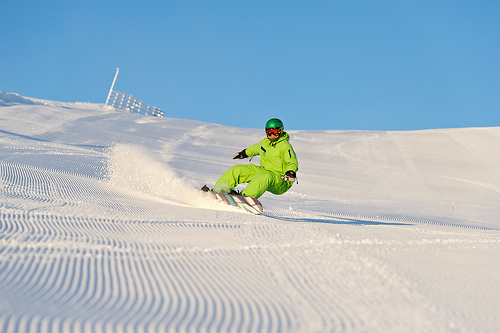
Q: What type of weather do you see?
A: It is clear.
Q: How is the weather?
A: It is clear.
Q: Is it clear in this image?
A: Yes, it is clear.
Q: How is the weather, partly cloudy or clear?
A: It is clear.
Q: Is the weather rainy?
A: No, it is clear.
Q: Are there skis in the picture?
A: No, there are no skis.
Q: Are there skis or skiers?
A: No, there are no skis or skiers.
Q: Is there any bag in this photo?
A: No, there are no bags.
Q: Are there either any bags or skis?
A: No, there are no bags or skis.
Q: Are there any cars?
A: No, there are no cars.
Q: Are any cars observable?
A: No, there are no cars.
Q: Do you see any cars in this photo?
A: No, there are no cars.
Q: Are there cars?
A: No, there are no cars.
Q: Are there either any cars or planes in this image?
A: No, there are no cars or planes.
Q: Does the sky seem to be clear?
A: Yes, the sky is clear.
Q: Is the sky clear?
A: Yes, the sky is clear.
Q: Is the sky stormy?
A: No, the sky is clear.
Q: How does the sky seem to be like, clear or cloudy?
A: The sky is clear.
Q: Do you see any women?
A: No, there are no women.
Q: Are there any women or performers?
A: No, there are no women or performers.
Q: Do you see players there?
A: No, there are no players.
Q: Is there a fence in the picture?
A: Yes, there is a fence.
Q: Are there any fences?
A: Yes, there is a fence.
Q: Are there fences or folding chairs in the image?
A: Yes, there is a fence.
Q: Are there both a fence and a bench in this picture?
A: No, there is a fence but no benches.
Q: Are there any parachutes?
A: No, there are no parachutes.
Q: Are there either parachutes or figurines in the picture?
A: No, there are no parachutes or figurines.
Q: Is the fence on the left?
A: Yes, the fence is on the left of the image.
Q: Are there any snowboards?
A: Yes, there is a snowboard.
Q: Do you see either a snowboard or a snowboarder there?
A: Yes, there is a snowboard.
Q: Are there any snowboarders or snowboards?
A: Yes, there is a snowboard.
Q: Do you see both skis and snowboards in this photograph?
A: No, there is a snowboard but no skis.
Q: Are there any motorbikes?
A: No, there are no motorbikes.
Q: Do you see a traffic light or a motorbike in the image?
A: No, there are no motorcycles or traffic lights.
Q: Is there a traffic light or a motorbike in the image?
A: No, there are no motorcycles or traffic lights.